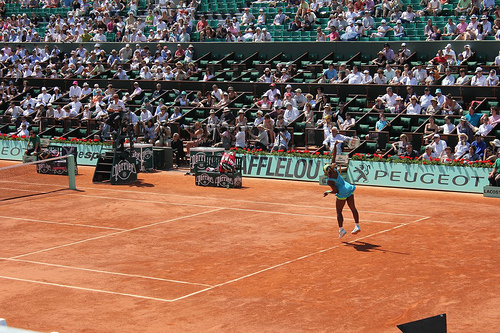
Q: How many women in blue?
A: One.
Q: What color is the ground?
A: Brown.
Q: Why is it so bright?
A: Sun light.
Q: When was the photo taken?
A: Day time.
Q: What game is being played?
A: Tennis.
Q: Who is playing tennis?
A: The woman.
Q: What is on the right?
A: The crowd.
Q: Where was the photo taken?
A: At a tennis match.